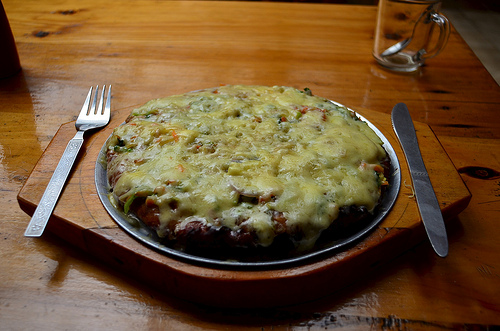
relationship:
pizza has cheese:
[103, 84, 393, 255] [103, 85, 392, 261]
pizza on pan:
[103, 84, 393, 255] [94, 98, 402, 273]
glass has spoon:
[373, 1, 447, 72] [381, 1, 437, 57]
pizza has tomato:
[103, 84, 393, 255] [145, 199, 157, 206]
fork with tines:
[24, 83, 111, 238] [80, 86, 112, 115]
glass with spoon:
[373, 1, 447, 72] [381, 1, 437, 57]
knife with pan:
[391, 101, 449, 255] [94, 98, 402, 273]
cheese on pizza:
[103, 85, 392, 261] [103, 84, 393, 255]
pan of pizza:
[94, 98, 402, 273] [103, 84, 393, 255]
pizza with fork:
[103, 84, 393, 255] [24, 83, 111, 238]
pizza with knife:
[103, 84, 393, 255] [391, 101, 449, 255]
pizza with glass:
[103, 84, 393, 255] [373, 1, 447, 72]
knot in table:
[59, 8, 79, 16] [0, 2, 499, 330]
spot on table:
[441, 106, 454, 111] [0, 2, 499, 330]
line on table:
[274, 310, 494, 329] [0, 2, 499, 330]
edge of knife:
[402, 101, 482, 256] [391, 101, 449, 255]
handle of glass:
[428, 14, 448, 52] [373, 1, 447, 72]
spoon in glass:
[381, 1, 437, 57] [373, 1, 447, 72]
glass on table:
[373, 1, 447, 72] [0, 2, 499, 330]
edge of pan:
[95, 128, 118, 223] [94, 98, 402, 273]